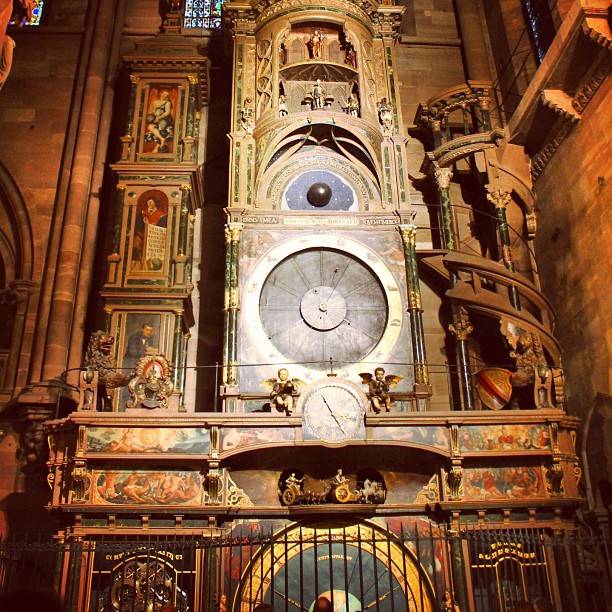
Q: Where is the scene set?
A: In a church.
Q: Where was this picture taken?
A: In front of an old building.